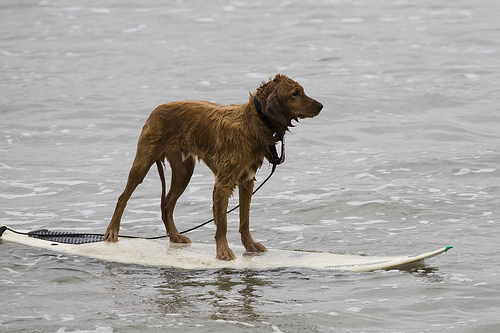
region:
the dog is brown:
[87, 22, 309, 214]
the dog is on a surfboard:
[157, 109, 364, 277]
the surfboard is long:
[88, 215, 418, 332]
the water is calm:
[84, 180, 298, 324]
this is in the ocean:
[80, 69, 345, 316]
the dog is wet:
[187, 76, 338, 163]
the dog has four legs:
[91, 136, 231, 256]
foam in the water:
[268, 320, 287, 332]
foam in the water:
[210, 314, 256, 328]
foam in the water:
[163, 310, 183, 317]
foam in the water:
[123, 315, 135, 324]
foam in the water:
[53, 323, 114, 331]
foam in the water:
[322, 308, 340, 318]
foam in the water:
[345, 303, 365, 313]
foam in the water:
[346, 198, 388, 207]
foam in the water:
[417, 217, 432, 226]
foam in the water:
[440, 216, 464, 223]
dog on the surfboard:
[103, 47, 308, 263]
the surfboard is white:
[29, 216, 442, 330]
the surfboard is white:
[8, 210, 468, 278]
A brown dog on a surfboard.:
[92, 70, 324, 262]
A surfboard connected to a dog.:
[1, 96, 299, 233]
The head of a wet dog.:
[246, 77, 321, 133]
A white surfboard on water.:
[3, 223, 467, 282]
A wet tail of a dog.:
[152, 155, 168, 208]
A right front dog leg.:
[206, 180, 233, 260]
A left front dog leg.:
[237, 170, 268, 258]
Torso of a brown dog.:
[174, 99, 258, 173]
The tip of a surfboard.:
[384, 239, 469, 285]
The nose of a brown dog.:
[310, 99, 330, 122]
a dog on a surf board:
[108, 69, 325, 260]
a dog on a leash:
[103, 73, 326, 259]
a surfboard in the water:
[1, 224, 455, 275]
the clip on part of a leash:
[259, 129, 289, 170]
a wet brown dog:
[101, 73, 325, 263]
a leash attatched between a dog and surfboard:
[2, 127, 285, 240]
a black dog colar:
[247, 90, 285, 133]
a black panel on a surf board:
[27, 225, 107, 245]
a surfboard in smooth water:
[2, 2, 497, 328]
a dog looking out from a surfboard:
[103, 71, 324, 262]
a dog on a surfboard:
[102, 74, 322, 269]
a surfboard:
[313, 252, 372, 271]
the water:
[43, 60, 107, 102]